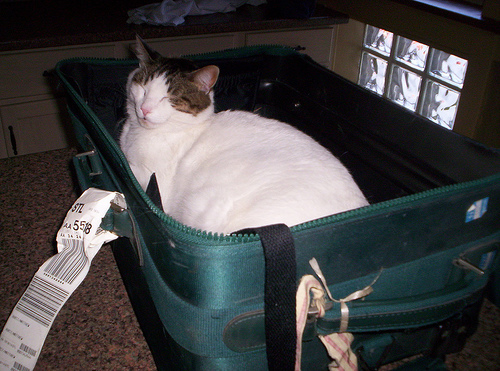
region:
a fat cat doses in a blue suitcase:
[113, 32, 360, 219]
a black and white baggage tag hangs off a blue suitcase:
[5, 188, 116, 368]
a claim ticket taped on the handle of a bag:
[5, 182, 127, 367]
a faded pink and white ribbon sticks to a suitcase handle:
[297, 274, 352, 369]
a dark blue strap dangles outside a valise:
[260, 226, 295, 368]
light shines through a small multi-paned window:
[349, 26, 479, 125]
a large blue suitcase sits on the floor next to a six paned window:
[57, 34, 478, 364]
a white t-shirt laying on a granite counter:
[130, 2, 245, 31]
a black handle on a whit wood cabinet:
[6, 124, 26, 154]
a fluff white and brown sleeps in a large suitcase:
[129, 36, 351, 231]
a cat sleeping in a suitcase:
[29, 43, 499, 333]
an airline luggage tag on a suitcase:
[14, 183, 131, 368]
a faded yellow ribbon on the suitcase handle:
[303, 267, 383, 341]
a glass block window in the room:
[356, 16, 468, 133]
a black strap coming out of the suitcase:
[219, 226, 316, 362]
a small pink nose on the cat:
[140, 105, 152, 120]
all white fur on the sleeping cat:
[205, 130, 310, 202]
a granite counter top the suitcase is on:
[9, 165, 59, 235]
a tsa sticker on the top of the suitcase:
[466, 196, 490, 229]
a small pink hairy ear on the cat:
[184, 58, 226, 93]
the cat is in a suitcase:
[58, 0, 498, 367]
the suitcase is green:
[51, 53, 495, 369]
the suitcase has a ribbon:
[311, 255, 376, 330]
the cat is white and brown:
[123, 36, 373, 235]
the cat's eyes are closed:
[131, 80, 181, 104]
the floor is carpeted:
[1, 152, 160, 368]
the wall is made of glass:
[363, 22, 468, 134]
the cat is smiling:
[130, 80, 188, 128]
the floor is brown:
[0, 149, 159, 369]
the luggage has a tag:
[1, 190, 123, 367]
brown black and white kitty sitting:
[119, 42, 368, 232]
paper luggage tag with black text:
[1, 183, 122, 367]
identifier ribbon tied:
[307, 256, 380, 334]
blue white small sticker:
[465, 197, 490, 219]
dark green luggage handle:
[313, 270, 494, 331]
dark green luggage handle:
[69, 149, 133, 238]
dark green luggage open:
[49, 45, 498, 366]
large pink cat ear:
[186, 62, 219, 92]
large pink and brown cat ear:
[133, 34, 157, 63]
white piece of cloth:
[130, 2, 244, 25]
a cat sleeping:
[125, 33, 360, 218]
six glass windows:
[351, 20, 468, 130]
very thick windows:
[357, 22, 458, 113]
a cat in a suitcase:
[43, 45, 497, 369]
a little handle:
[6, 120, 19, 159]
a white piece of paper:
[2, 185, 126, 366]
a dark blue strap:
[227, 221, 305, 366]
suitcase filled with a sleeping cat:
[46, 34, 493, 365]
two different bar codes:
[16, 227, 95, 328]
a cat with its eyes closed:
[113, 31, 217, 127]